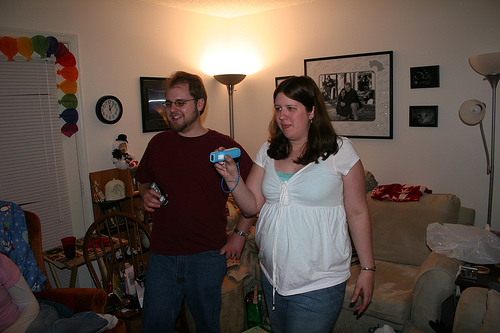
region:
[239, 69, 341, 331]
woman wearing a white shirt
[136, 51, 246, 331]
man in glasses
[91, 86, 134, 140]
black clock on wall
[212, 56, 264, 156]
lamp that is on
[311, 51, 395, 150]
large black and white picture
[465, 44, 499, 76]
lamp shade closest to the top right picture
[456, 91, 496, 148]
bottom lamp shade in right corner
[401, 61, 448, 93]
top small black picture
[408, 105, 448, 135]
bottom small black picture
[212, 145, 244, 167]
light blue object in her hand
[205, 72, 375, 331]
a woman standing in living room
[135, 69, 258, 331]
a man standing in living room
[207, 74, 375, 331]
a woman playing a video game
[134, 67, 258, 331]
a man playing a video game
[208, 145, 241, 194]
a Wii video game controller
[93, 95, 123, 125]
a black wall clock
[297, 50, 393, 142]
a matted and framed photo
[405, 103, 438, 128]
a framed photo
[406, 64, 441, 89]
a framed photo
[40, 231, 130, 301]
a small folding table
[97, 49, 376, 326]
a male and female holding wii controller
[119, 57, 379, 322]
a man and a pregnant woman holding a wii controller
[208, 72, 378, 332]
a woman holding a blue wii controller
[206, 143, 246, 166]
blue wii control a woman is holding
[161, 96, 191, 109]
an eyeglasses a guy is wearing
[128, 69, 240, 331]
a guy in jeans holding a wii controller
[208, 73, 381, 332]
a pregnant woman wearing jeans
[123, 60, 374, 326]
a man and a woman in the family room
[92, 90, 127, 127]
a clock on the wall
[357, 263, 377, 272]
a wrist watch a woman is wearing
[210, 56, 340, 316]
The woman is holding a wii remote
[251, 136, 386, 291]
The woman is wearing a white shirt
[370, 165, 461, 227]
Blanket on top of the couch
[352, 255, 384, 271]
The woman has a watch on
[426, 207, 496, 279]
Plastic bag near the lamp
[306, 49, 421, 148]
Picture hanging on the wall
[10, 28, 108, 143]
Decorative cut outs near the window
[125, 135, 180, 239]
Man holding a wii remote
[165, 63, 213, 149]
The man has short brown hair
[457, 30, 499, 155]
Tall lamp near the wall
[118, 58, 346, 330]
people playing video game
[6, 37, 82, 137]
border with balloons on door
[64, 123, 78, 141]
colorful balloon on border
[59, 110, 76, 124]
colorful balloon on border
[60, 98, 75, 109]
colorful balloon on border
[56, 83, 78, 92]
colorful balloon on border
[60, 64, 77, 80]
colorful balloon on border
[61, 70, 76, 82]
colorful balloon on border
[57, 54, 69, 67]
colorful balloon on border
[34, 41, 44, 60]
colorful balloon on border